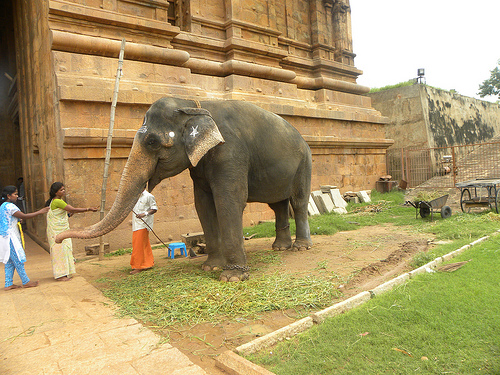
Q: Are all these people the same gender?
A: No, they are both male and female.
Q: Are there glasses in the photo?
A: No, there are no glasses.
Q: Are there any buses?
A: No, there are no buses.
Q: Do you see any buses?
A: No, there are no buses.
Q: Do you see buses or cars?
A: No, there are no buses or cars.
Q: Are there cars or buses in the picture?
A: No, there are no buses or cars.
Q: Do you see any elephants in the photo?
A: Yes, there is an elephant.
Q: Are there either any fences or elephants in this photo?
A: Yes, there is an elephant.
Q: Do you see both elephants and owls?
A: No, there is an elephant but no owls.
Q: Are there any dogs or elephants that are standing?
A: Yes, the elephant is standing.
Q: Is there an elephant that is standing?
A: Yes, there is an elephant that is standing.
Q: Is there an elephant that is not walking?
A: Yes, there is an elephant that is standing.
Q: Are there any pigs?
A: No, there are no pigs.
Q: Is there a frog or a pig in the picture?
A: No, there are no pigs or frogs.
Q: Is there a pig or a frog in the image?
A: No, there are no pigs or frogs.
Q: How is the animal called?
A: The animal is an elephant.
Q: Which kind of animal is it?
A: The animal is an elephant.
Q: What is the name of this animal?
A: This is an elephant.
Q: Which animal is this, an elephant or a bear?
A: This is an elephant.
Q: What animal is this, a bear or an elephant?
A: This is an elephant.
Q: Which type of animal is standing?
A: The animal is an elephant.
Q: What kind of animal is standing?
A: The animal is an elephant.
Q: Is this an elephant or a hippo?
A: This is an elephant.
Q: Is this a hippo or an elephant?
A: This is an elephant.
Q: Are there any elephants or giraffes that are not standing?
A: No, there is an elephant but it is standing.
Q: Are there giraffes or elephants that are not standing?
A: No, there is an elephant but it is standing.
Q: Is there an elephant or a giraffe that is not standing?
A: No, there is an elephant but it is standing.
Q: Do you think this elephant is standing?
A: Yes, the elephant is standing.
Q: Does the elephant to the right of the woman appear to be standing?
A: Yes, the elephant is standing.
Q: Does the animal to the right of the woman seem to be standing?
A: Yes, the elephant is standing.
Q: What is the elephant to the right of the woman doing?
A: The elephant is standing.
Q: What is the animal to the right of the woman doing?
A: The elephant is standing.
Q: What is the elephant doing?
A: The elephant is standing.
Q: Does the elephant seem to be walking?
A: No, the elephant is standing.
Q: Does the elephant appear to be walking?
A: No, the elephant is standing.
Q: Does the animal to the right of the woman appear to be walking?
A: No, the elephant is standing.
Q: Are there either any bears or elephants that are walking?
A: No, there is an elephant but it is standing.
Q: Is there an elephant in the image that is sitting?
A: No, there is an elephant but it is standing.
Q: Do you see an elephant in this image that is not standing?
A: No, there is an elephant but it is standing.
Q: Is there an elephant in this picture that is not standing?
A: No, there is an elephant but it is standing.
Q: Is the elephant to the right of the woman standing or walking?
A: The elephant is standing.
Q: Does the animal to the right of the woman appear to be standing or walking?
A: The elephant is standing.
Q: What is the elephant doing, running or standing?
A: The elephant is standing.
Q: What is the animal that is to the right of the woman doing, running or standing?
A: The elephant is standing.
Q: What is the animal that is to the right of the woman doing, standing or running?
A: The elephant is standing.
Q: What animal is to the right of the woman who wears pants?
A: The animal is an elephant.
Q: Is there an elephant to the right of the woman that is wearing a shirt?
A: Yes, there is an elephant to the right of the woman.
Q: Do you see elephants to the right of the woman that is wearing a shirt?
A: Yes, there is an elephant to the right of the woman.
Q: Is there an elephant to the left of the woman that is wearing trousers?
A: No, the elephant is to the right of the woman.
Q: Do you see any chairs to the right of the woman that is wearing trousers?
A: No, there is an elephant to the right of the woman.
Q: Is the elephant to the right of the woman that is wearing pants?
A: Yes, the elephant is to the right of the woman.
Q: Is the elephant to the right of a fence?
A: No, the elephant is to the right of the woman.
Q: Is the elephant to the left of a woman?
A: No, the elephant is to the right of a woman.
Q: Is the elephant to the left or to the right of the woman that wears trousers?
A: The elephant is to the right of the woman.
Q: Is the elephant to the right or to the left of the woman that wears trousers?
A: The elephant is to the right of the woman.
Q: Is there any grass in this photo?
A: Yes, there is grass.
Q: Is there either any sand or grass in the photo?
A: Yes, there is grass.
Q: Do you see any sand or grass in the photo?
A: Yes, there is grass.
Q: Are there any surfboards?
A: No, there are no surfboards.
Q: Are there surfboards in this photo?
A: No, there are no surfboards.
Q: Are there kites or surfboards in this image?
A: No, there are no surfboards or kites.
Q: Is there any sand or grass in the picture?
A: Yes, there is grass.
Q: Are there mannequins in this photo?
A: No, there are no mannequins.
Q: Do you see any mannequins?
A: No, there are no mannequins.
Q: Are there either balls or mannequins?
A: No, there are no mannequins or balls.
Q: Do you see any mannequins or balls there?
A: No, there are no mannequins or balls.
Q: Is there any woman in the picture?
A: Yes, there is a woman.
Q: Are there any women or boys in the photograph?
A: Yes, there is a woman.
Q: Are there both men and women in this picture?
A: Yes, there are both a woman and a man.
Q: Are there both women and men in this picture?
A: Yes, there are both a woman and a man.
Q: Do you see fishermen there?
A: No, there are no fishermen.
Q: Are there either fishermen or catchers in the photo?
A: No, there are no fishermen or catchers.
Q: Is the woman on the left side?
A: Yes, the woman is on the left of the image.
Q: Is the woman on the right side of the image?
A: No, the woman is on the left of the image.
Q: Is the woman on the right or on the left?
A: The woman is on the left of the image.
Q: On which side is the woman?
A: The woman is on the left of the image.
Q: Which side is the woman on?
A: The woman is on the left of the image.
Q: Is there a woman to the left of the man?
A: Yes, there is a woman to the left of the man.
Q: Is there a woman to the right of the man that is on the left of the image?
A: No, the woman is to the left of the man.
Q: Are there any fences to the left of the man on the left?
A: No, there is a woman to the left of the man.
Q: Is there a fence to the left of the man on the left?
A: No, there is a woman to the left of the man.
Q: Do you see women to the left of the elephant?
A: Yes, there is a woman to the left of the elephant.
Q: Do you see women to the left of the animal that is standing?
A: Yes, there is a woman to the left of the elephant.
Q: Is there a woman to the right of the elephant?
A: No, the woman is to the left of the elephant.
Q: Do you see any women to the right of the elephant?
A: No, the woman is to the left of the elephant.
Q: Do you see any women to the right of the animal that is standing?
A: No, the woman is to the left of the elephant.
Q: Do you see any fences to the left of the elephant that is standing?
A: No, there is a woman to the left of the elephant.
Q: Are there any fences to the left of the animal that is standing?
A: No, there is a woman to the left of the elephant.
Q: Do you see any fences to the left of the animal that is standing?
A: No, there is a woman to the left of the elephant.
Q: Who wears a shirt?
A: The woman wears a shirt.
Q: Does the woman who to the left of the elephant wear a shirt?
A: Yes, the woman wears a shirt.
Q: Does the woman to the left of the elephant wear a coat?
A: No, the woman wears a shirt.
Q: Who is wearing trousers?
A: The woman is wearing trousers.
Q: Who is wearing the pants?
A: The woman is wearing trousers.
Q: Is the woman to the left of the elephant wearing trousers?
A: Yes, the woman is wearing trousers.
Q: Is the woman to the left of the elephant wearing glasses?
A: No, the woman is wearing trousers.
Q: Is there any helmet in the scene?
A: No, there are no helmets.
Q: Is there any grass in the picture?
A: Yes, there is grass.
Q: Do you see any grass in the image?
A: Yes, there is grass.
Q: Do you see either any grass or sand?
A: Yes, there is grass.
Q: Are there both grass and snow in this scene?
A: No, there is grass but no snow.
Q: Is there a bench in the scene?
A: No, there are no benches.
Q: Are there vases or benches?
A: No, there are no benches or vases.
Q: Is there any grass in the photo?
A: Yes, there is grass.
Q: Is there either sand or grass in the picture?
A: Yes, there is grass.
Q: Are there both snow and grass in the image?
A: No, there is grass but no snow.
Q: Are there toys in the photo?
A: No, there are no toys.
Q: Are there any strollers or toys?
A: No, there are no toys or strollers.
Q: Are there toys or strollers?
A: No, there are no toys or strollers.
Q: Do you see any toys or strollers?
A: No, there are no toys or strollers.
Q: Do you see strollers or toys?
A: No, there are no toys or strollers.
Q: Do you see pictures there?
A: No, there are no pictures.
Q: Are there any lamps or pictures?
A: No, there are no pictures or lamps.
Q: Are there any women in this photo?
A: Yes, there is a woman.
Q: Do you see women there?
A: Yes, there is a woman.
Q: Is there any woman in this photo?
A: Yes, there is a woman.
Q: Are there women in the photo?
A: Yes, there is a woman.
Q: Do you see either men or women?
A: Yes, there is a woman.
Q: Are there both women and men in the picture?
A: Yes, there are both a woman and a man.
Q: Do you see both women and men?
A: Yes, there are both a woman and a man.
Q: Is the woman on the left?
A: Yes, the woman is on the left of the image.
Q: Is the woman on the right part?
A: No, the woman is on the left of the image.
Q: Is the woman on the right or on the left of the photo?
A: The woman is on the left of the image.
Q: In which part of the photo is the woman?
A: The woman is on the left of the image.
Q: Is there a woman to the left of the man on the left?
A: Yes, there is a woman to the left of the man.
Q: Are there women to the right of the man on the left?
A: No, the woman is to the left of the man.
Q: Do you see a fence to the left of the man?
A: No, there is a woman to the left of the man.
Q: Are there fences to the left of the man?
A: No, there is a woman to the left of the man.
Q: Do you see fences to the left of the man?
A: No, there is a woman to the left of the man.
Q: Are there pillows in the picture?
A: No, there are no pillows.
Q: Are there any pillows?
A: No, there are no pillows.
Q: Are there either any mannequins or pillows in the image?
A: No, there are no pillows or mannequins.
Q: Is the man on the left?
A: Yes, the man is on the left of the image.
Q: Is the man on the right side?
A: No, the man is on the left of the image.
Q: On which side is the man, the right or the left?
A: The man is on the left of the image.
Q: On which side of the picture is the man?
A: The man is on the left of the image.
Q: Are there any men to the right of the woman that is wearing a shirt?
A: Yes, there is a man to the right of the woman.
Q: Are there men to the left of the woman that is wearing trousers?
A: No, the man is to the right of the woman.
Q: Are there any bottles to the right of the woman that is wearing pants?
A: No, there is a man to the right of the woman.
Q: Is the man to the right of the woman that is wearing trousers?
A: Yes, the man is to the right of the woman.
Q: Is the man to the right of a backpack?
A: No, the man is to the right of the woman.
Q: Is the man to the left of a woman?
A: No, the man is to the right of a woman.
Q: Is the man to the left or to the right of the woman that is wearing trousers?
A: The man is to the right of the woman.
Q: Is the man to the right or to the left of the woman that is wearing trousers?
A: The man is to the right of the woman.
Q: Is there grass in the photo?
A: Yes, there is grass.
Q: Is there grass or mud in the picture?
A: Yes, there is grass.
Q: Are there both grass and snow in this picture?
A: No, there is grass but no snow.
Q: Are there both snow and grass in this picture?
A: No, there is grass but no snow.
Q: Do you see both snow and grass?
A: No, there is grass but no snow.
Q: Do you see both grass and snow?
A: No, there is grass but no snow.